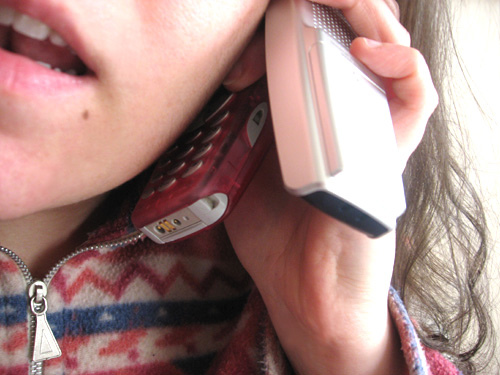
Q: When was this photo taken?
A: Yesterday.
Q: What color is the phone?
A: White.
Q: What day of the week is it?
A: Monday.